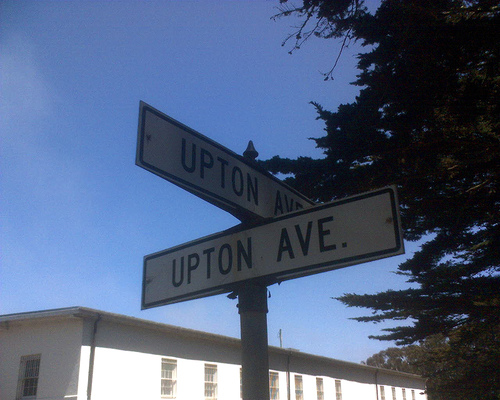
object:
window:
[269, 372, 278, 400]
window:
[294, 374, 302, 400]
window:
[202, 362, 216, 397]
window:
[160, 358, 175, 396]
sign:
[140, 183, 398, 308]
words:
[276, 215, 335, 264]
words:
[180, 137, 259, 205]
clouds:
[316, 325, 347, 352]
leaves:
[483, 2, 496, 23]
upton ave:
[170, 216, 338, 291]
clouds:
[23, 0, 55, 15]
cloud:
[0, 70, 40, 84]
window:
[16, 355, 38, 398]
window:
[335, 381, 341, 398]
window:
[402, 388, 405, 397]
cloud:
[3, 24, 26, 41]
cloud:
[2, 131, 53, 157]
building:
[0, 306, 428, 399]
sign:
[135, 99, 354, 216]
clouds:
[154, 218, 178, 234]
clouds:
[102, 290, 131, 306]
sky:
[1, 2, 479, 313]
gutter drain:
[87, 314, 103, 399]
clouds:
[5, 284, 50, 302]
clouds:
[118, 246, 134, 267]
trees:
[223, 3, 497, 399]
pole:
[239, 139, 267, 398]